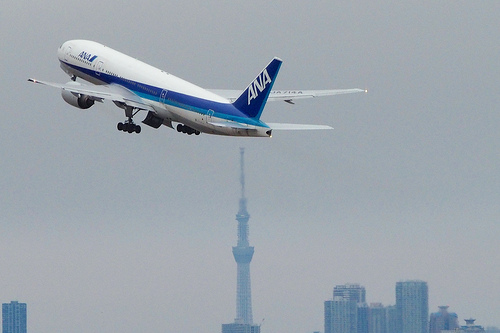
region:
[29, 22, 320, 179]
the plane is flying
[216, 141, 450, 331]
tower and buildings in the distance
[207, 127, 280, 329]
tower and buildings in the distance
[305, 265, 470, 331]
tower and buildings in the distance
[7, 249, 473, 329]
tower and buildings in the distance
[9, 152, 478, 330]
tower and buildings in the distance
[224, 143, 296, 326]
a tower in the distance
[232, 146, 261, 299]
a tower in the distance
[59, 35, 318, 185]
the plane is white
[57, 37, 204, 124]
the plane is white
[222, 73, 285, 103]
ana logo on plane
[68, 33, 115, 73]
logo on the plane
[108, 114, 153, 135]
wheels of the plane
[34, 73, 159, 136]
left wing of the plane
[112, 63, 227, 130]
blue stripes on plane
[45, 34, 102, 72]
front of the white plane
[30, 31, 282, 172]
airplane about to take off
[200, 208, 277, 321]
skyscraper in distance in back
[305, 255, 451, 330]
more skyscrapers in back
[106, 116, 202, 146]
two sets of wheels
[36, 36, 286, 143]
A plane just took off.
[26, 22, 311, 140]
The plane is in the air.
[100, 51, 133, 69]
The top of the plane is white.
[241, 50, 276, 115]
The tail of the plane is blue and white.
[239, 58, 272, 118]
The tail says ANA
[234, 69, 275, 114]
The lettering is in white.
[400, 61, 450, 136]
The sky is hazy.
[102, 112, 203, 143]
The wheels of the plane are still down.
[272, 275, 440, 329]
Buildings in the background.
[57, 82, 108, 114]
One engine on the wing.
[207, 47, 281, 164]
plane's tail is blue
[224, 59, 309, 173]
plane's tail is blue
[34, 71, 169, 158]
plane's wing is white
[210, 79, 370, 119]
plane's wing is white